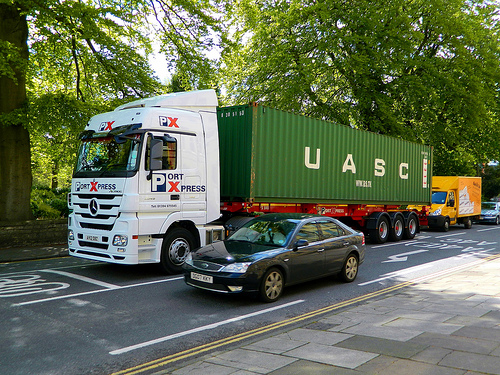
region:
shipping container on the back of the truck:
[231, 107, 444, 204]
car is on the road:
[183, 204, 367, 291]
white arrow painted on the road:
[376, 240, 429, 270]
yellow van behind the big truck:
[436, 174, 488, 224]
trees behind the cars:
[234, 21, 422, 110]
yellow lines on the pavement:
[202, 328, 274, 344]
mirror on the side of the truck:
[145, 124, 167, 173]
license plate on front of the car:
[182, 267, 217, 287]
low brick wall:
[10, 218, 50, 253]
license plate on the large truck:
[79, 227, 102, 243]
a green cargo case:
[221, 100, 436, 205]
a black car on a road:
[181, 214, 361, 310]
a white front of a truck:
[64, 92, 218, 259]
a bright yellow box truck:
[414, 169, 484, 233]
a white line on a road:
[103, 279, 303, 358]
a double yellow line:
[136, 302, 353, 370]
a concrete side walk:
[304, 323, 497, 373]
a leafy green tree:
[318, 15, 499, 116]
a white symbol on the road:
[6, 266, 77, 308]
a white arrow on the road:
[381, 240, 428, 275]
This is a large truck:
[64, 70, 436, 262]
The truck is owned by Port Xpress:
[137, 161, 207, 194]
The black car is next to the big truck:
[187, 200, 381, 310]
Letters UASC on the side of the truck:
[290, 122, 423, 197]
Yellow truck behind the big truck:
[417, 155, 495, 235]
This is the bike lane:
[2, 256, 89, 298]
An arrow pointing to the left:
[377, 237, 432, 267]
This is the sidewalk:
[246, 275, 481, 374]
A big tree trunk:
[2, 5, 42, 232]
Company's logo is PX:
[145, 105, 186, 129]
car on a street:
[179, 206, 380, 309]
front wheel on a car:
[259, 263, 288, 305]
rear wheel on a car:
[339, 250, 362, 285]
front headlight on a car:
[218, 259, 254, 279]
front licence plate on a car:
[187, 268, 218, 287]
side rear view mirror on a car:
[289, 236, 314, 253]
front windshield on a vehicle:
[71, 128, 146, 182]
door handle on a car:
[314, 245, 327, 258]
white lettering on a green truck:
[299, 141, 415, 196]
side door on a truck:
[134, 125, 185, 238]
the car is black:
[165, 200, 373, 312]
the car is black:
[183, 202, 357, 307]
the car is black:
[165, 198, 374, 307]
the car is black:
[176, 197, 378, 308]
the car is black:
[177, 202, 374, 318]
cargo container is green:
[215, 73, 445, 223]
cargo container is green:
[226, 92, 433, 212]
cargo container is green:
[220, 88, 434, 210]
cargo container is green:
[214, 80, 442, 230]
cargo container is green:
[211, 77, 437, 228]